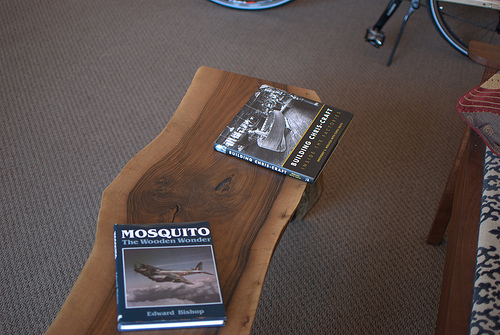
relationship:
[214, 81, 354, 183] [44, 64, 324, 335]
book on coffee table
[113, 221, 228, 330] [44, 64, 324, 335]
book on coffee table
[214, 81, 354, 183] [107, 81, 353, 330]
book on books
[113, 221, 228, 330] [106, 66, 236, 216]
book on table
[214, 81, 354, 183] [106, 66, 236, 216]
book on table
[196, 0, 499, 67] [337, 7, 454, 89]
bike has kick stand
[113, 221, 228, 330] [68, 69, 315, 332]
book on table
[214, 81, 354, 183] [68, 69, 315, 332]
book on table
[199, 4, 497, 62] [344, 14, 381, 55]
bike has pedal